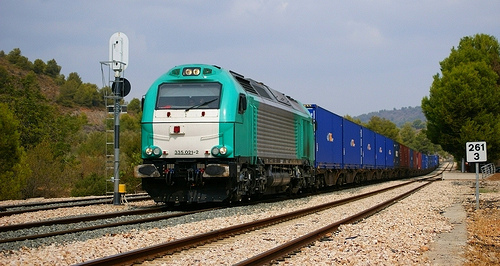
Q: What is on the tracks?
A: A train.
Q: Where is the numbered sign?
A: On then right.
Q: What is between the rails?
A: Gravel.